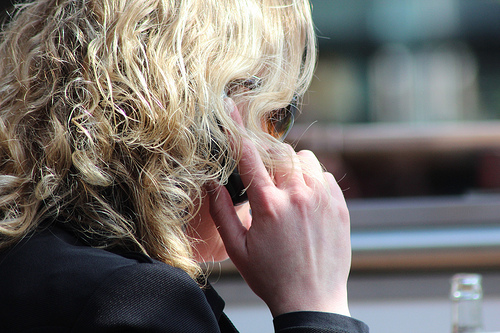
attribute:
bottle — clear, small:
[457, 267, 486, 330]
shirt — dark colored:
[6, 191, 380, 331]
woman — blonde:
[6, 0, 375, 330]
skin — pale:
[213, 99, 351, 316]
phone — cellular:
[206, 69, 256, 207]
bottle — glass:
[451, 273, 481, 330]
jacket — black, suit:
[0, 180, 374, 328]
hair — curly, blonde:
[2, 0, 319, 283]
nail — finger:
[223, 99, 231, 114]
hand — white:
[200, 93, 358, 318]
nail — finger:
[219, 95, 234, 112]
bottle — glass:
[451, 275, 486, 329]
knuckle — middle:
[292, 180, 314, 214]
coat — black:
[0, 185, 364, 330]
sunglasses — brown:
[263, 107, 295, 137]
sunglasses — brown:
[270, 106, 295, 135]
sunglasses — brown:
[263, 101, 294, 137]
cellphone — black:
[202, 135, 252, 206]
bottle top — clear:
[449, 273, 481, 329]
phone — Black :
[183, 102, 254, 203]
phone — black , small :
[188, 98, 254, 208]